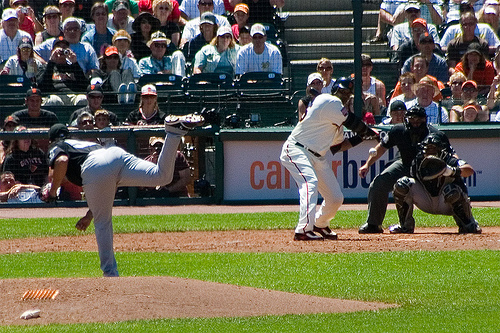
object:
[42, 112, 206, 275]
pitcher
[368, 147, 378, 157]
ball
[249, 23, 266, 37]
cap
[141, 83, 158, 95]
cap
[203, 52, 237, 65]
top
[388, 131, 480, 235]
catcher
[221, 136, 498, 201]
ad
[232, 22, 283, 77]
man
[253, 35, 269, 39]
sunglasses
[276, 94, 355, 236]
uniform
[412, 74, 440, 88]
hat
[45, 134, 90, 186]
jersey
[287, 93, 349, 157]
shirt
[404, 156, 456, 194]
mitt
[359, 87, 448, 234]
umpire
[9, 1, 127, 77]
fans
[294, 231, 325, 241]
shoes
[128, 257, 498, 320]
field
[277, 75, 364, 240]
players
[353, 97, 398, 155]
bat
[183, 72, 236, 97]
seats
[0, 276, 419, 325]
mound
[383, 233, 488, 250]
home plate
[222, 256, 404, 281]
grass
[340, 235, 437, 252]
dirt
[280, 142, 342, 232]
pants